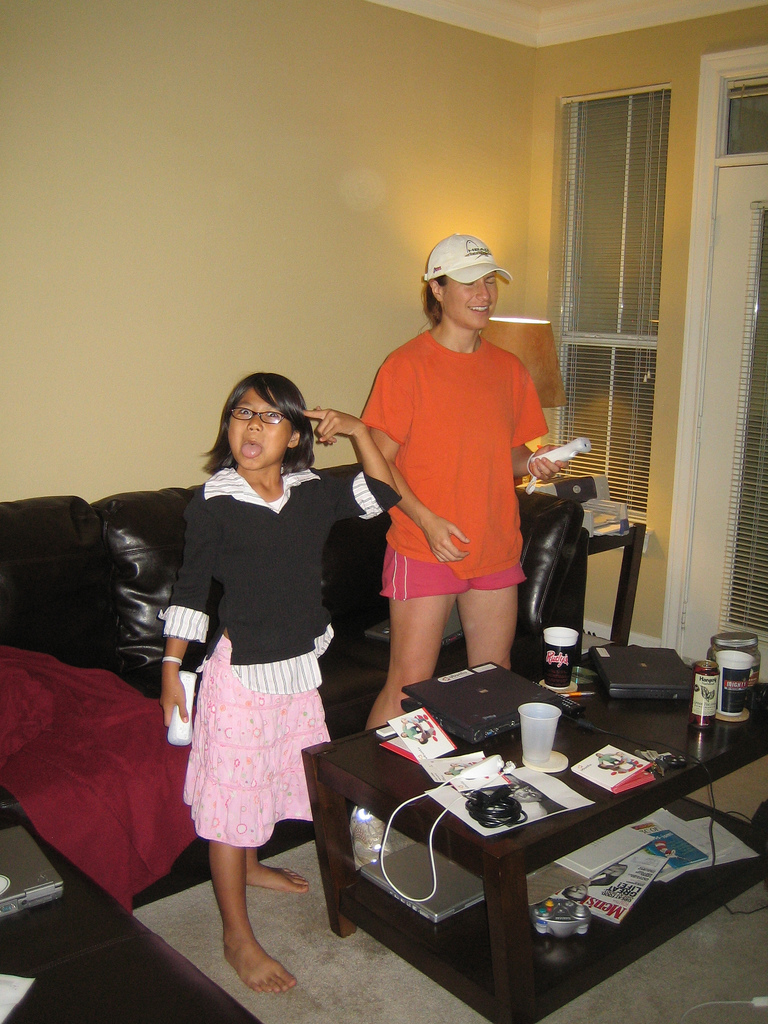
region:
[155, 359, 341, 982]
Young girl playing video game.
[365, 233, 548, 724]
A woman playing video games.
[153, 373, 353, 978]
Young girl wearing black sweater.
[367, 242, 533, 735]
A woman wearing pink shorts.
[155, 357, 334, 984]
A young girl wearing glasses.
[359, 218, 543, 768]
A woman wearing a white hat.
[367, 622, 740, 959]
A cluttered wooden coffee table.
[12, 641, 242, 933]
Red blanket laying on couch.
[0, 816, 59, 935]
A laptop sitting closed.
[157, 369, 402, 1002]
little girl standing holding white wii mote wearing pink skirt and black shirt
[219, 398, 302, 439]
girl wearing reading glasses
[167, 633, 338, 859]
girl wearing a pink dress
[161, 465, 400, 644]
girl wearing a black shirt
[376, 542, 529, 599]
girl wearing pink shorts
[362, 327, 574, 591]
girl wearing orange tee shirt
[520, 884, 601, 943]
game controller under the table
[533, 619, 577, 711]
cup on the table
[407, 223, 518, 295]
woman wearing a hat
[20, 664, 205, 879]
red sheet on the sofa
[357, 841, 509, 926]
laptop under the table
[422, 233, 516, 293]
a white baseball cap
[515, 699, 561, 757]
a white plastic cup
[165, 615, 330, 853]
a girl's pink skirt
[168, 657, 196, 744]
a white game controller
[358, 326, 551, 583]
a woman's orange short sleeve shirt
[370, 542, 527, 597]
a woman's pink and white shorts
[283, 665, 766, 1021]
a brown table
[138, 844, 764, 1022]
beige living room carpet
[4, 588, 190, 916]
a red blanket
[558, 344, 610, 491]
building has a window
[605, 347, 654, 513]
building has a window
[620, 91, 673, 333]
building has a window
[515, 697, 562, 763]
clear cup on table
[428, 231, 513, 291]
white hat on woman's head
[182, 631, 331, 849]
pink skirt on girl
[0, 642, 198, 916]
red blanket on couch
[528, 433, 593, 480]
WII control in woman's hand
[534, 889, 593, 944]
gray game controller on table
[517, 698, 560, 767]
empty clear plastic cup on table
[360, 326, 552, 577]
orange shirt on woman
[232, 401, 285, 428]
glasses on girl's face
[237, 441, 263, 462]
tongue sticking out on girl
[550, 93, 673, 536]
white blinds on window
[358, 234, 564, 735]
person wearing white hat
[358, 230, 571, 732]
person holding white controller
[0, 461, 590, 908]
black sofa is leather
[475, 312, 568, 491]
lamp next to black sofa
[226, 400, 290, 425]
girl wearing prescription glasses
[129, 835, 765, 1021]
rug beneath coffee table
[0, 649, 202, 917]
red blanket on top of sofa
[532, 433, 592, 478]
woman holding white controller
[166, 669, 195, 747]
girl holding white controller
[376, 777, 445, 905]
white cord on top of coffee table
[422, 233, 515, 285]
the hat is white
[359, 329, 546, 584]
the shirt is orange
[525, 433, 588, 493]
the wiimote is white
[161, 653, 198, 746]
the wiimote is white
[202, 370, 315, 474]
the hair is dark brown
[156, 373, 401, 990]
the girl is wearing glasses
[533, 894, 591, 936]
the controller is silver